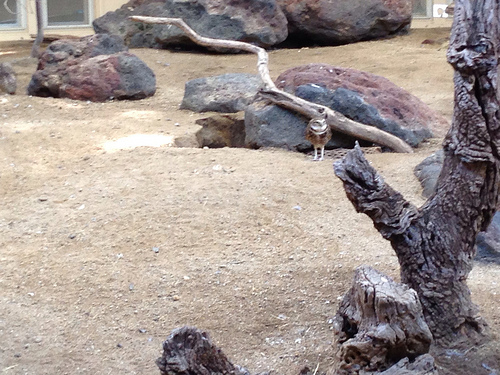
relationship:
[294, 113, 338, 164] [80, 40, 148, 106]
owl on rock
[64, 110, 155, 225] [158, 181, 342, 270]
dirt on ground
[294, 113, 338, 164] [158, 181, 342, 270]
owl on ground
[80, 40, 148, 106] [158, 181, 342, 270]
rock on ground